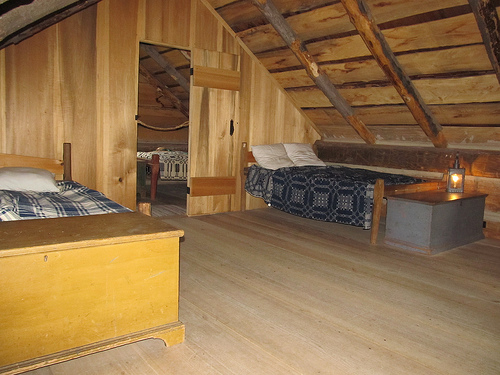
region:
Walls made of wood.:
[3, 5, 243, 185]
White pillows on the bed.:
[251, 140, 326, 165]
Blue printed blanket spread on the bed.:
[250, 167, 390, 207]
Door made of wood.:
[185, 45, 240, 215]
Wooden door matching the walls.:
[185, 45, 240, 216]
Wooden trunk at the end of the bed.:
[5, 205, 185, 355]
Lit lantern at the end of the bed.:
[441, 150, 466, 195]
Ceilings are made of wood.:
[7, 5, 492, 120]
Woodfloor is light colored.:
[185, 260, 495, 360]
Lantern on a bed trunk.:
[382, 150, 484, 251]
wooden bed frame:
[229, 145, 406, 245]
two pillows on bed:
[248, 133, 325, 176]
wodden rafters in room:
[268, 23, 450, 108]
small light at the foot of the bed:
[445, 157, 478, 211]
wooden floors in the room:
[270, 261, 349, 346]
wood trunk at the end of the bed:
[0, 208, 193, 365]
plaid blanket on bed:
[0, 175, 139, 222]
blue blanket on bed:
[264, 158, 375, 223]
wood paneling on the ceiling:
[287, 25, 444, 125]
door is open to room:
[125, 36, 200, 224]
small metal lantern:
[440, 148, 471, 199]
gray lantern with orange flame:
[441, 150, 470, 205]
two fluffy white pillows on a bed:
[247, 137, 329, 172]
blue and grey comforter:
[266, 160, 432, 237]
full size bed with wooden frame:
[237, 133, 462, 250]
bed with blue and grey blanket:
[237, 132, 457, 252]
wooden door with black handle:
[183, 38, 248, 218]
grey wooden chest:
[381, 180, 489, 257]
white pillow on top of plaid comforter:
[1, 158, 61, 197]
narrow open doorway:
[131, 28, 196, 226]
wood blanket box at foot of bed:
[5, 211, 212, 371]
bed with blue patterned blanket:
[230, 128, 448, 238]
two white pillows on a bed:
[230, 129, 340, 191]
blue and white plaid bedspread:
[1, 163, 142, 229]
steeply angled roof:
[185, 0, 499, 188]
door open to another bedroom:
[120, 31, 245, 221]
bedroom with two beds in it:
[11, 76, 418, 319]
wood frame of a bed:
[234, 132, 459, 250]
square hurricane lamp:
[427, 153, 488, 224]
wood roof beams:
[230, 1, 496, 173]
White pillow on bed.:
[8, 167, 93, 232]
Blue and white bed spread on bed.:
[35, 187, 103, 242]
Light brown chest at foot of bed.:
[63, 232, 145, 338]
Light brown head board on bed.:
[30, 146, 110, 196]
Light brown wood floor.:
[235, 243, 328, 356]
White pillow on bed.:
[259, 137, 294, 199]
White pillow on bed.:
[279, 115, 314, 180]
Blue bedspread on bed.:
[301, 167, 373, 242]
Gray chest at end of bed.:
[390, 193, 490, 243]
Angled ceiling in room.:
[273, 48, 456, 217]